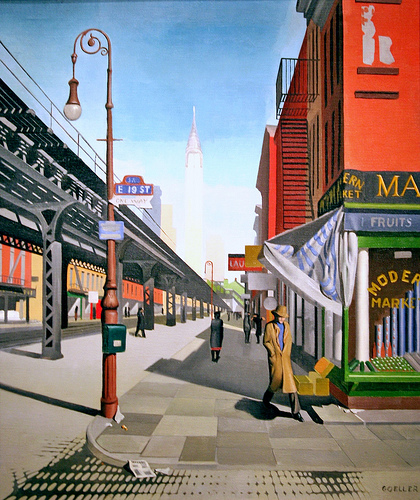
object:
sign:
[99, 219, 124, 241]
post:
[101, 33, 118, 416]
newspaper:
[128, 459, 156, 477]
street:
[1, 460, 418, 499]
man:
[262, 304, 304, 423]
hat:
[271, 305, 290, 318]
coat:
[264, 318, 296, 399]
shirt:
[275, 321, 284, 352]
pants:
[289, 392, 301, 414]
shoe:
[293, 411, 304, 424]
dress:
[210, 347, 221, 350]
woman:
[209, 310, 223, 364]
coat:
[210, 316, 223, 348]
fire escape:
[282, 57, 315, 229]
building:
[256, 2, 420, 405]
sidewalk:
[85, 396, 418, 465]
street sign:
[114, 176, 152, 196]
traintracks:
[1, 78, 22, 202]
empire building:
[186, 103, 203, 263]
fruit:
[387, 367, 390, 370]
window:
[364, 231, 419, 357]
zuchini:
[360, 361, 364, 372]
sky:
[2, 2, 286, 100]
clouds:
[218, 115, 252, 161]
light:
[64, 79, 82, 122]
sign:
[316, 166, 420, 210]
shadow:
[144, 319, 286, 402]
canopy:
[258, 210, 345, 314]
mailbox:
[102, 325, 126, 353]